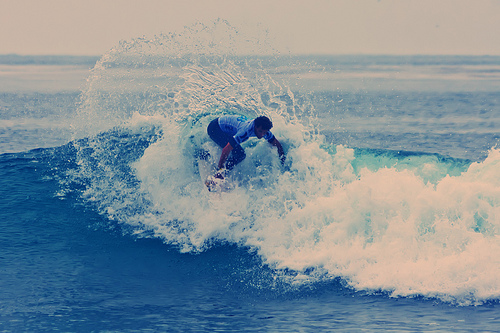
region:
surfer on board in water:
[184, 94, 301, 201]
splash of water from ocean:
[98, 30, 230, 87]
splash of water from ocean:
[63, 97, 100, 125]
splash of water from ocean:
[286, 88, 317, 120]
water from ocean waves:
[344, 222, 403, 266]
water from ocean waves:
[423, 208, 469, 250]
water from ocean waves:
[430, 177, 475, 205]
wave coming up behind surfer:
[34, 143, 84, 181]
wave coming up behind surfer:
[354, 135, 390, 169]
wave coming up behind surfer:
[106, 119, 170, 164]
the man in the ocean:
[166, 85, 314, 255]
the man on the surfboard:
[185, 105, 300, 205]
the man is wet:
[195, 100, 305, 205]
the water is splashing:
[95, 55, 405, 330]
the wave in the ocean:
[335, 140, 495, 275]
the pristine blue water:
[70, 230, 155, 305]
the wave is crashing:
[281, 135, 491, 305]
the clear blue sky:
[357, 10, 447, 32]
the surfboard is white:
[175, 155, 245, 216]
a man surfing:
[185, 118, 301, 186]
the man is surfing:
[200, 97, 287, 187]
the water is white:
[385, 204, 422, 266]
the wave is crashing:
[349, 166, 445, 271]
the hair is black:
[258, 114, 267, 133]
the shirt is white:
[217, 107, 249, 144]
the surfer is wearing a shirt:
[220, 109, 254, 143]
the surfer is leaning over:
[195, 96, 293, 203]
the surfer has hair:
[255, 117, 271, 130]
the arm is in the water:
[257, 130, 292, 170]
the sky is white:
[305, 10, 468, 46]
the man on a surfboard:
[177, 93, 313, 228]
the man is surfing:
[152, 72, 288, 224]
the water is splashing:
[107, 46, 277, 101]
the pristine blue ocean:
[15, 215, 133, 295]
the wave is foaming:
[320, 160, 465, 280]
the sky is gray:
[347, 12, 401, 39]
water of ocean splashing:
[196, 22, 244, 72]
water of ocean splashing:
[99, 67, 133, 95]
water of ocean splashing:
[88, 155, 115, 185]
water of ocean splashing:
[326, 145, 359, 180]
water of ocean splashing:
[350, 166, 369, 185]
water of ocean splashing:
[426, 190, 460, 225]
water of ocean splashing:
[106, 203, 122, 227]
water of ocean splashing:
[208, 228, 226, 253]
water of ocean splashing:
[261, 248, 288, 275]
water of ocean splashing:
[293, 106, 315, 141]